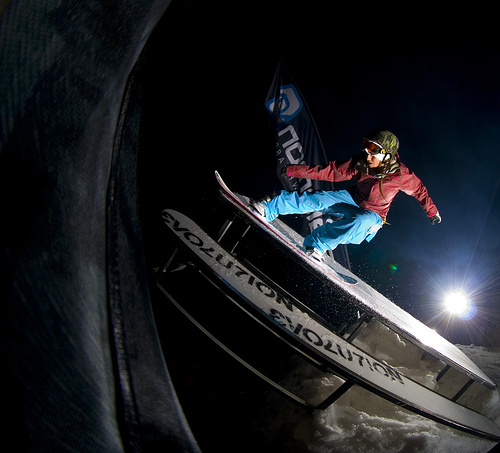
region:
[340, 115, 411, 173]
man's hat is green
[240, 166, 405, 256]
man's pants are blue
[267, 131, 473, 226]
man's jacket is red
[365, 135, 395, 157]
goggles on man's head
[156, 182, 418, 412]
black letters on object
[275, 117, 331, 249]
white letters on wall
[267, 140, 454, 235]
man is wearing gloves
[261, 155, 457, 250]
the gloves are black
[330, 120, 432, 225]
person is looking down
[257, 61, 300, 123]
blue and white logo on wall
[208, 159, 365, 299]
The man on a snowboard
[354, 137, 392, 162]
The man has on snow goggles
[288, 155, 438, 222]
The man is wearing a jacket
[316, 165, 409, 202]
The jacket is the color red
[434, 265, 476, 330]
The light behind the bench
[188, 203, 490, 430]
The bench is outside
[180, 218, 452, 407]
The bench is the color white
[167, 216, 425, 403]
The bench has black writing on it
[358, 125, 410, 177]
The head of the man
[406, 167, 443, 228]
The arm of the man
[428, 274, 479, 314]
The light is on.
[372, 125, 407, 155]
The helmet is green.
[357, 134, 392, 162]
His googles are white.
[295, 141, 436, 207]
His jacket is red.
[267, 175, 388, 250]
His pants are blue.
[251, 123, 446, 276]
He is surfing.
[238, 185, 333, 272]
His boots are white.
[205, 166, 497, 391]
He is on a snow board.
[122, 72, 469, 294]
He is doing a trick.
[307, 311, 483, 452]
The ground is snow covered.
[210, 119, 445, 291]
Man is on a snowboard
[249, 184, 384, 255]
Man is wearing pants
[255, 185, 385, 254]
Man is wearing blue pants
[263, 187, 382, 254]
Man is wearing light blue pants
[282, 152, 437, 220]
Man is wearing a jacket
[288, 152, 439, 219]
Man is wearing a red jacket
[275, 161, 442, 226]
Man is wearing gloves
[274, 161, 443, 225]
Man is wearing black gloves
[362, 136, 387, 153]
Man is wearing goggles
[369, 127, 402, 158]
Man is wearing a helmet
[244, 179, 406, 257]
Blue pants on snowboarder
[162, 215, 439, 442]
White bench with black lettering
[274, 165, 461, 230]
Red jacket on snowboarder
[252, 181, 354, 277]
White shoes on snowboarder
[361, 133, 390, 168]
White goggles on snowboarder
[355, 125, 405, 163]
Green hat on snowboarder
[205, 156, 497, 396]
Snowboarder using a white snowboard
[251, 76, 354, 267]
Black sign behind the snowboarder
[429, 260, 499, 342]
Light shining in the dark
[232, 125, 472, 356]
Snowboarder doing a trick